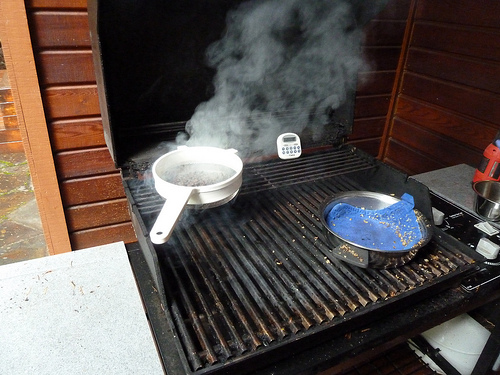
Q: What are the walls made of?
A: Wood.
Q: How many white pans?
A: One.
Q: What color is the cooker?
A: Black.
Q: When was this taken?
A: During the day.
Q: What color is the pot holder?
A: Blue.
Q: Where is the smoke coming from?
A: The white pan.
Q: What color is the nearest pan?
A: Silver.